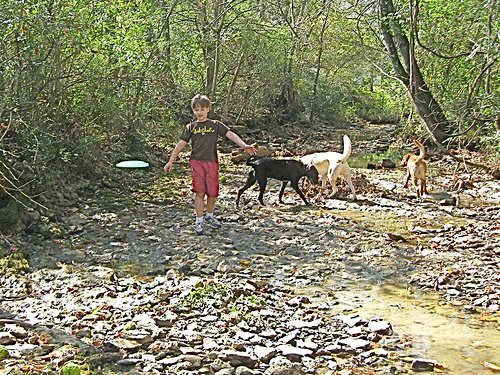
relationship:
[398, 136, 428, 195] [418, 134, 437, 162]
dog wagging h tail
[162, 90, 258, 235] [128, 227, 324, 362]
boy walking on ground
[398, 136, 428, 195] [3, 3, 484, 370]
dog sniffing around woods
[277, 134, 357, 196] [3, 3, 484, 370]
dog sniffing around woods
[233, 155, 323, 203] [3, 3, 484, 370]
black dog sniffing around woods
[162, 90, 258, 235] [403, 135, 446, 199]
boy has dog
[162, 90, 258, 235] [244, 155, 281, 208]
boy has dog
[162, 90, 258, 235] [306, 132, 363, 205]
boy has dog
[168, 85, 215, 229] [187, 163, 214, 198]
boy wearing shorts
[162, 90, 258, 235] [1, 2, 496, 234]
boy walking in woods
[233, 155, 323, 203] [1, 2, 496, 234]
black dog walking in woods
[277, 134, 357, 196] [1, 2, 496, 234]
dog walking in woods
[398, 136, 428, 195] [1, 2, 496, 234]
dog walking in woods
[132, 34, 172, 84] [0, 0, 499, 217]
forest of trees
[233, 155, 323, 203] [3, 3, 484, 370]
black dog walking in a woods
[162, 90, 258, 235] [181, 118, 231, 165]
boy wearing helmet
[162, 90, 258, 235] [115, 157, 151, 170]
boy throwing frisbee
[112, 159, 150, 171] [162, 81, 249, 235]
frisbee being thrown by boy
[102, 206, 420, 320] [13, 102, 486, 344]
rocks covering ground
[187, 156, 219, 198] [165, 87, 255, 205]
pants being worn by boy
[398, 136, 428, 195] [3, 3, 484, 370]
dog running in woods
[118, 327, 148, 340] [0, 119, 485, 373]
stones on ground